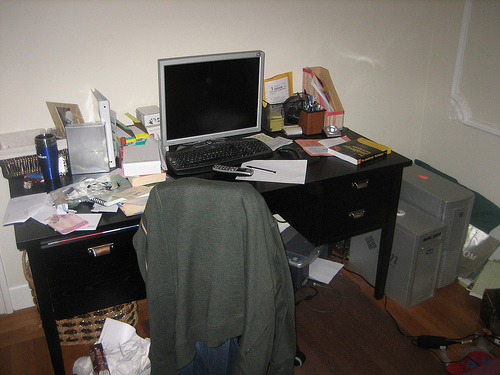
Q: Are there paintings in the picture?
A: No, there are no paintings.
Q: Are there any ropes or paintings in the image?
A: No, there are no paintings or ropes.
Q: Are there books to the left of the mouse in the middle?
A: Yes, there is a book to the left of the mouse.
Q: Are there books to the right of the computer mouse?
A: No, the book is to the left of the computer mouse.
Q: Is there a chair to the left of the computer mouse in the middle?
A: No, there is a book to the left of the computer mouse.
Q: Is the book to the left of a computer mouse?
A: Yes, the book is to the left of a computer mouse.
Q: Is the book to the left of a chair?
A: No, the book is to the left of a computer mouse.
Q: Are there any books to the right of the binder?
A: Yes, there is a book to the right of the binder.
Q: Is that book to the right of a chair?
A: No, the book is to the right of the binder.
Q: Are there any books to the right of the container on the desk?
A: Yes, there is a book to the right of the container.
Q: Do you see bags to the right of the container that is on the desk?
A: No, there is a book to the right of the container.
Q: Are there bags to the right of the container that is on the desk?
A: No, there is a book to the right of the container.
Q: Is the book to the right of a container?
A: Yes, the book is to the right of a container.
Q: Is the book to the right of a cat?
A: No, the book is to the right of a container.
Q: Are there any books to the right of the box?
A: Yes, there is a book to the right of the box.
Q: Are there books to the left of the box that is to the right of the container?
A: No, the book is to the right of the box.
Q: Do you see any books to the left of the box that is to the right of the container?
A: No, the book is to the right of the box.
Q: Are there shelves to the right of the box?
A: No, there is a book to the right of the box.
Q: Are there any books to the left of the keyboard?
A: Yes, there is a book to the left of the keyboard.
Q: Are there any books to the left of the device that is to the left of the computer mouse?
A: Yes, there is a book to the left of the keyboard.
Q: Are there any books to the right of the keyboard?
A: No, the book is to the left of the keyboard.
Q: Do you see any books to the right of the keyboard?
A: No, the book is to the left of the keyboard.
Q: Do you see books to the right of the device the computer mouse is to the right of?
A: No, the book is to the left of the keyboard.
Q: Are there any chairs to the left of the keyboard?
A: No, there is a book to the left of the keyboard.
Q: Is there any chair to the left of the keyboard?
A: No, there is a book to the left of the keyboard.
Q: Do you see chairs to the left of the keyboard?
A: No, there is a book to the left of the keyboard.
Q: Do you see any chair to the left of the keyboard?
A: No, there is a book to the left of the keyboard.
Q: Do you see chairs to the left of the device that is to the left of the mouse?
A: No, there is a book to the left of the keyboard.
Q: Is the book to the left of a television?
A: No, the book is to the left of the keyboard.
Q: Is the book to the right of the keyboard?
A: No, the book is to the left of the keyboard.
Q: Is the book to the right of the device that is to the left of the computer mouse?
A: No, the book is to the left of the keyboard.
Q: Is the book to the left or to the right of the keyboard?
A: The book is to the left of the keyboard.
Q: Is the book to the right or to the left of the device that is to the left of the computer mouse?
A: The book is to the left of the keyboard.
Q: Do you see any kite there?
A: No, there are no kites.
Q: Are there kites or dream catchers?
A: No, there are no kites or dream catchers.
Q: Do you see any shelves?
A: No, there are no shelves.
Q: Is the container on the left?
A: Yes, the container is on the left of the image.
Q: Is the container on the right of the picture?
A: No, the container is on the left of the image.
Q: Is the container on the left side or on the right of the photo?
A: The container is on the left of the image.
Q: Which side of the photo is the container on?
A: The container is on the left of the image.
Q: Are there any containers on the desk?
A: Yes, there is a container on the desk.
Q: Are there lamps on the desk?
A: No, there is a container on the desk.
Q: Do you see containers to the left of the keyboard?
A: Yes, there is a container to the left of the keyboard.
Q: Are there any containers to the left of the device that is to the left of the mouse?
A: Yes, there is a container to the left of the keyboard.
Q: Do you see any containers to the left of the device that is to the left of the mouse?
A: Yes, there is a container to the left of the keyboard.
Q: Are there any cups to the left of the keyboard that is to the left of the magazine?
A: No, there is a container to the left of the keyboard.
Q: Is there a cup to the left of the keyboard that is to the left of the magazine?
A: No, there is a container to the left of the keyboard.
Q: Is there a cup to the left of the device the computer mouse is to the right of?
A: No, there is a container to the left of the keyboard.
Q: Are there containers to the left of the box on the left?
A: Yes, there is a container to the left of the box.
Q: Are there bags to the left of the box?
A: No, there is a container to the left of the box.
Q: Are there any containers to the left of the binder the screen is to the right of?
A: Yes, there is a container to the left of the binder.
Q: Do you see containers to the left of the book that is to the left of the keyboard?
A: Yes, there is a container to the left of the book.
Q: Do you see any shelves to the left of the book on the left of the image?
A: No, there is a container to the left of the book.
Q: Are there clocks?
A: No, there are no clocks.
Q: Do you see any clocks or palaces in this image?
A: No, there are no clocks or palaces.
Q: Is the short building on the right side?
A: Yes, the tower is on the right of the image.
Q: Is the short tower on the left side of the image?
A: No, the tower is on the right of the image.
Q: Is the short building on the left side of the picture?
A: No, the tower is on the right of the image.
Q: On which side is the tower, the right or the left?
A: The tower is on the right of the image.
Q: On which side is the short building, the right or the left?
A: The tower is on the right of the image.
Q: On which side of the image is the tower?
A: The tower is on the right of the image.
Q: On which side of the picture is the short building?
A: The tower is on the right of the image.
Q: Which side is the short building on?
A: The tower is on the right of the image.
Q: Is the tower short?
A: Yes, the tower is short.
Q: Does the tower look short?
A: Yes, the tower is short.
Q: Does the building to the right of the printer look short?
A: Yes, the tower is short.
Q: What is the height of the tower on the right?
A: The tower is short.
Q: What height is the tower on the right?
A: The tower is short.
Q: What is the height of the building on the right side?
A: The tower is short.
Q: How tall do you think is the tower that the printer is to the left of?
A: The tower is short.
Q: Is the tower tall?
A: No, the tower is short.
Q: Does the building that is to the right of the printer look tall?
A: No, the tower is short.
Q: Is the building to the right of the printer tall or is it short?
A: The tower is short.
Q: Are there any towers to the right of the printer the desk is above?
A: Yes, there is a tower to the right of the printer.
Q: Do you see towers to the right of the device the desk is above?
A: Yes, there is a tower to the right of the printer.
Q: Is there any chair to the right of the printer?
A: No, there is a tower to the right of the printer.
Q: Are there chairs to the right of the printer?
A: No, there is a tower to the right of the printer.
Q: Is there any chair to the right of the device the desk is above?
A: No, there is a tower to the right of the printer.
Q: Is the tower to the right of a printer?
A: Yes, the tower is to the right of a printer.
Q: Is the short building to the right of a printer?
A: Yes, the tower is to the right of a printer.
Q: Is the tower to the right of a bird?
A: No, the tower is to the right of a printer.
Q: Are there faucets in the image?
A: No, there are no faucets.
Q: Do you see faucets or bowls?
A: No, there are no faucets or bowls.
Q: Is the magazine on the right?
A: Yes, the magazine is on the right of the image.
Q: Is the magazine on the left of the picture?
A: No, the magazine is on the right of the image.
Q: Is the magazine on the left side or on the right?
A: The magazine is on the right of the image.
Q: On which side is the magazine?
A: The magazine is on the right of the image.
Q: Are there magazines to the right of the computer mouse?
A: Yes, there is a magazine to the right of the computer mouse.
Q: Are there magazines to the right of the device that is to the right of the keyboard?
A: Yes, there is a magazine to the right of the computer mouse.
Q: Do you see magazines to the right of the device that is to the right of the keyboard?
A: Yes, there is a magazine to the right of the computer mouse.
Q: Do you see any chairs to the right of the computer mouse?
A: No, there is a magazine to the right of the computer mouse.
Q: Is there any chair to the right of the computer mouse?
A: No, there is a magazine to the right of the computer mouse.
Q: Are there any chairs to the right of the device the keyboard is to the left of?
A: No, there is a magazine to the right of the computer mouse.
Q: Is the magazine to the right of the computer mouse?
A: Yes, the magazine is to the right of the computer mouse.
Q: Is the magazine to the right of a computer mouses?
A: No, the magazine is to the right of the computer mouse.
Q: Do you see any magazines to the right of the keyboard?
A: Yes, there is a magazine to the right of the keyboard.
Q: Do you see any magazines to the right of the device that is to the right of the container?
A: Yes, there is a magazine to the right of the keyboard.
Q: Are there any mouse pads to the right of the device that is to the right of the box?
A: No, there is a magazine to the right of the keyboard.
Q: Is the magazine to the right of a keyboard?
A: Yes, the magazine is to the right of a keyboard.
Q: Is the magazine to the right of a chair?
A: No, the magazine is to the right of a keyboard.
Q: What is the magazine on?
A: The magazine is on the desk.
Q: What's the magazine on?
A: The magazine is on the desk.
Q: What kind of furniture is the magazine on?
A: The magazine is on the desk.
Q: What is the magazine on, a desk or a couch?
A: The magazine is on a desk.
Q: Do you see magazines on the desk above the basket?
A: Yes, there is a magazine on the desk.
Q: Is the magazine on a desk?
A: Yes, the magazine is on a desk.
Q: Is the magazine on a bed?
A: No, the magazine is on a desk.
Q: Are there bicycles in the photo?
A: No, there are no bicycles.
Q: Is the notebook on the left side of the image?
A: Yes, the notebook is on the left of the image.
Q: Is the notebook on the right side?
A: No, the notebook is on the left of the image.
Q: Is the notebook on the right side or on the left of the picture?
A: The notebook is on the left of the image.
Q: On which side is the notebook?
A: The notebook is on the left of the image.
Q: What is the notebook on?
A: The notebook is on the desk.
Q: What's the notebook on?
A: The notebook is on the desk.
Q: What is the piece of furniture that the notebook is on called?
A: The piece of furniture is a desk.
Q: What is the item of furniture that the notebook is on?
A: The piece of furniture is a desk.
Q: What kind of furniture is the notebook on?
A: The notebook is on the desk.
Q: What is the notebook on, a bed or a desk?
A: The notebook is on a desk.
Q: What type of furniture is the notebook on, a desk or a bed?
A: The notebook is on a desk.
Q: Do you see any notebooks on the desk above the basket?
A: Yes, there is a notebook on the desk.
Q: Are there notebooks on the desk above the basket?
A: Yes, there is a notebook on the desk.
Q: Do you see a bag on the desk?
A: No, there is a notebook on the desk.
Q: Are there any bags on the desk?
A: No, there is a notebook on the desk.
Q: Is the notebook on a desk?
A: Yes, the notebook is on a desk.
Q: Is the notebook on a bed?
A: No, the notebook is on a desk.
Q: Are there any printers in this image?
A: Yes, there is a printer.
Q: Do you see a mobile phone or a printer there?
A: Yes, there is a printer.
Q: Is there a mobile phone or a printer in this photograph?
A: Yes, there is a printer.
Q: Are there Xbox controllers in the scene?
A: No, there are no Xbox controllers.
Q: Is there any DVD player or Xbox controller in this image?
A: No, there are no Xbox controllers or DVD players.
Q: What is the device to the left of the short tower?
A: The device is a printer.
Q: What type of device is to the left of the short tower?
A: The device is a printer.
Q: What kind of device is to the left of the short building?
A: The device is a printer.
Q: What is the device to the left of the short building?
A: The device is a printer.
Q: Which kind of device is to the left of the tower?
A: The device is a printer.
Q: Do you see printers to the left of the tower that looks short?
A: Yes, there is a printer to the left of the tower.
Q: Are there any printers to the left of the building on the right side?
A: Yes, there is a printer to the left of the tower.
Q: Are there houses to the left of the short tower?
A: No, there is a printer to the left of the tower.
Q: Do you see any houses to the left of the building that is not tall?
A: No, there is a printer to the left of the tower.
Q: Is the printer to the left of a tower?
A: Yes, the printer is to the left of a tower.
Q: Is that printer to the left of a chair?
A: No, the printer is to the left of a tower.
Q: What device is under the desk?
A: The device is a printer.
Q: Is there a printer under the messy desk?
A: Yes, there is a printer under the desk.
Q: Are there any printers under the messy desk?
A: Yes, there is a printer under the desk.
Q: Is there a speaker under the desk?
A: No, there is a printer under the desk.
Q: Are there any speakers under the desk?
A: No, there is a printer under the desk.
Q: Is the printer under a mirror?
A: No, the printer is under the desk.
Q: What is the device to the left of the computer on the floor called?
A: The device is a printer.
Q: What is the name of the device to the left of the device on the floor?
A: The device is a printer.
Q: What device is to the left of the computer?
A: The device is a printer.